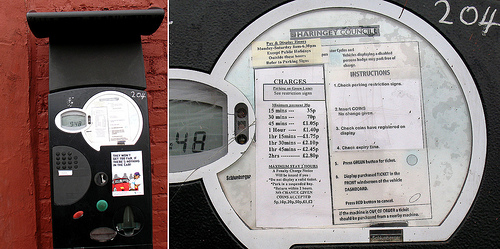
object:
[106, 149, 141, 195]
sticker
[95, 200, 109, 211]
button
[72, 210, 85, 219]
button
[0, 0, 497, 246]
meter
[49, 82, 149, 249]
town meter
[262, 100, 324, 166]
prices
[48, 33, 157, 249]
black box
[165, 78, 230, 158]
screen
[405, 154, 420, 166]
circle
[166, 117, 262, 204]
crack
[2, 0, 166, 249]
bricks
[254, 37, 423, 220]
paper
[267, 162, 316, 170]
writing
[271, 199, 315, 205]
writing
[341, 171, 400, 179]
writing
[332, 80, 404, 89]
writing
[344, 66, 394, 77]
writing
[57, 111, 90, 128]
timer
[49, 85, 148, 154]
circle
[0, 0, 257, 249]
device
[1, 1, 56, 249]
brick wall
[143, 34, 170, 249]
brick wall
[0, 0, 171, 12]
brick wall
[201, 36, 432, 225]
scale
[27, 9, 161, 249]
machine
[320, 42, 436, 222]
instructions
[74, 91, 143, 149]
sticker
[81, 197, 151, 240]
slots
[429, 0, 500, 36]
handwritten numbers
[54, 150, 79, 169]
buttons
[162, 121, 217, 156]
digital numbers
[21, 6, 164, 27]
top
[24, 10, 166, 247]
parking meter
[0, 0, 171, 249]
wall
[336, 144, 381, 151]
writings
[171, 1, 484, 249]
parking meter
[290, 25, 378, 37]
name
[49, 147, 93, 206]
control panel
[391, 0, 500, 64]
corner